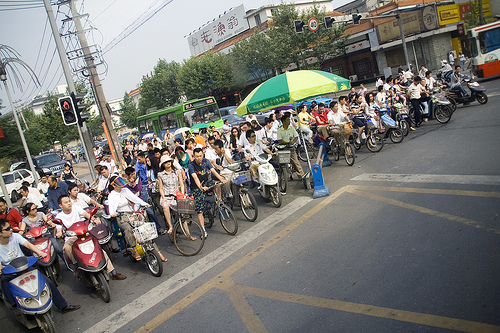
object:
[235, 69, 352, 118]
umbrella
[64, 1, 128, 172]
pole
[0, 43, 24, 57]
wires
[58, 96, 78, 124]
light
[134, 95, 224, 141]
bus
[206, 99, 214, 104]
lights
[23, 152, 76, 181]
jeep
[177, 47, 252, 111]
trees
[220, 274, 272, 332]
lines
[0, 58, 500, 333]
road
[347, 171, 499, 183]
markings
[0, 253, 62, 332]
scooter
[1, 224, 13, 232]
sunglasses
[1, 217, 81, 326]
person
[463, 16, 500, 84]
bus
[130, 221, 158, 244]
basket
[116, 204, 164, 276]
bike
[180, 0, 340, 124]
buildings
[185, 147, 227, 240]
people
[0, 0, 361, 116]
sky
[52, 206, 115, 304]
bike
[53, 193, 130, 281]
man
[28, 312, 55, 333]
wheel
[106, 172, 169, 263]
woman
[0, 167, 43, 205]
car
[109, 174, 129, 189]
hat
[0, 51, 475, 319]
group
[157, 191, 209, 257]
cyclist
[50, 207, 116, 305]
motorcyclists